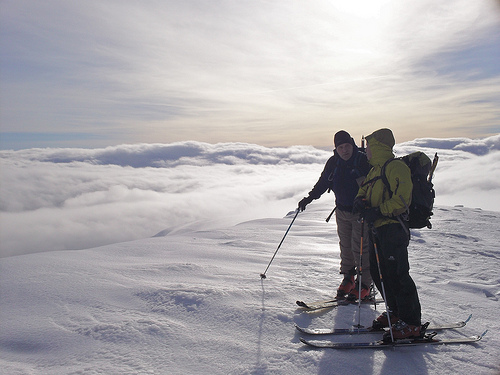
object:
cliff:
[1, 318, 396, 354]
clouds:
[70, 146, 181, 193]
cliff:
[5, 165, 200, 308]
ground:
[44, 354, 207, 375]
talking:
[301, 124, 438, 332]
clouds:
[27, 101, 82, 132]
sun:
[247, 100, 340, 148]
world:
[60, 17, 486, 331]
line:
[14, 214, 284, 375]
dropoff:
[1, 142, 274, 375]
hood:
[362, 155, 405, 245]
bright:
[85, 55, 304, 194]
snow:
[449, 248, 483, 301]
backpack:
[403, 151, 432, 228]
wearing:
[372, 135, 434, 304]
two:
[258, 198, 487, 349]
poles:
[366, 219, 394, 353]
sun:
[288, 8, 399, 59]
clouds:
[439, 19, 486, 44]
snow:
[68, 318, 119, 359]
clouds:
[26, 14, 202, 28]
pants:
[371, 224, 422, 327]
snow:
[123, 274, 205, 318]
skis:
[291, 314, 473, 333]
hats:
[331, 131, 352, 144]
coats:
[306, 150, 365, 211]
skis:
[301, 332, 489, 351]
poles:
[265, 196, 315, 272]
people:
[298, 127, 439, 342]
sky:
[382, 38, 473, 70]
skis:
[296, 298, 359, 311]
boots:
[336, 275, 353, 297]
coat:
[356, 157, 409, 224]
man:
[354, 128, 439, 341]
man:
[297, 131, 373, 300]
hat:
[368, 123, 426, 144]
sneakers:
[335, 279, 353, 300]